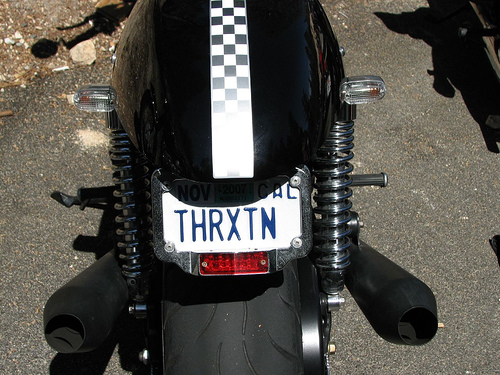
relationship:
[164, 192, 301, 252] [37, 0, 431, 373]
plate on motorcycle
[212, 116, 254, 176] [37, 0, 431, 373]
white on motorcycle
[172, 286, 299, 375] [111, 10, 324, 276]
tire in back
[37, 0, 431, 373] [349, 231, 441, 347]
bike has a muffler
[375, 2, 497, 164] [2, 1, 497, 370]
shadow on ground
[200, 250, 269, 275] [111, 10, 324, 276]
light on back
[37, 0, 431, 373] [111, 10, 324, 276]
motorcycle from back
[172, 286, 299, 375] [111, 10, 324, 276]
tire on back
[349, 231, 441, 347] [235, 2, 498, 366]
exhaust on right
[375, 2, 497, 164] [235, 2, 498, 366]
shadow to right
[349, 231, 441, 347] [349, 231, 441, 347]
pipe for exhaust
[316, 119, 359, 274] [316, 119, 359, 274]
absorber of spring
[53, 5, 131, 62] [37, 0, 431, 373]
handle of bike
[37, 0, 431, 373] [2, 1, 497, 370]
motorcycle on a road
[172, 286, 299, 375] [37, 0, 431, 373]
tire of motorcycle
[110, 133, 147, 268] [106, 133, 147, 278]
coil for coil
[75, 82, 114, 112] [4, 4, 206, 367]
signal for left turn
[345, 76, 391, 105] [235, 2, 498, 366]
signal for right turn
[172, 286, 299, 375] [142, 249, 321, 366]
grooves are on tire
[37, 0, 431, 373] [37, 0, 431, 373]
motorcycle has back